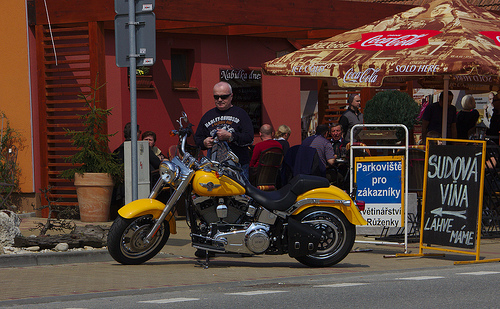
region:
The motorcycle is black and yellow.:
[102, 110, 370, 287]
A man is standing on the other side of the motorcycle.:
[96, 74, 378, 281]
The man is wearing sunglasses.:
[181, 73, 267, 273]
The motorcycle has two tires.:
[105, 102, 370, 278]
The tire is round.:
[281, 196, 357, 271]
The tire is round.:
[91, 197, 176, 272]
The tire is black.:
[104, 191, 183, 286]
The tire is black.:
[261, 181, 366, 281]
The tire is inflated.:
[280, 183, 367, 272]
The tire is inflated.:
[93, 180, 192, 275]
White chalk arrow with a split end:
[426, 203, 470, 222]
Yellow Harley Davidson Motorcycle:
[98, 110, 374, 272]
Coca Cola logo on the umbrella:
[340, 64, 382, 86]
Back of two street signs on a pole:
[109, 1, 160, 236]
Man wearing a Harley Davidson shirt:
[185, 75, 254, 246]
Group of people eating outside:
[104, 63, 499, 248]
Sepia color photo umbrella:
[259, 0, 499, 103]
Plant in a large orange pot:
[50, 76, 136, 230]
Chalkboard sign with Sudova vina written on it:
[407, 129, 490, 273]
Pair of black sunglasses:
[207, 90, 233, 102]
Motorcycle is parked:
[95, 110, 366, 267]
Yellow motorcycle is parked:
[105, 106, 360, 264]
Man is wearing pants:
[200, 152, 257, 190]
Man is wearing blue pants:
[194, 147, 257, 244]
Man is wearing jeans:
[198, 147, 251, 247]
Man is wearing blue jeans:
[200, 152, 254, 247]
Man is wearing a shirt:
[193, 104, 257, 153]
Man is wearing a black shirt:
[185, 105, 261, 167]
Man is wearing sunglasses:
[210, 91, 236, 102]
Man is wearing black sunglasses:
[212, 87, 235, 100]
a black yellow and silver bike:
[102, 123, 365, 278]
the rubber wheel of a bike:
[107, 208, 167, 258]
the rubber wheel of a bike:
[283, 203, 356, 265]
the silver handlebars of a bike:
[176, 124, 225, 172]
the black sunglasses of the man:
[212, 92, 232, 102]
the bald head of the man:
[213, 79, 231, 112]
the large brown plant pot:
[73, 170, 113, 218]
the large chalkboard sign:
[422, 139, 481, 254]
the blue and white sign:
[356, 158, 403, 233]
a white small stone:
[48, 240, 70, 250]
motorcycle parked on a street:
[96, 105, 376, 275]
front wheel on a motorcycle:
[100, 194, 177, 268]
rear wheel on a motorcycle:
[279, 182, 362, 271]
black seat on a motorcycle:
[239, 177, 299, 212]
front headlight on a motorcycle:
[156, 157, 181, 186]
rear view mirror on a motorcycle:
[216, 147, 244, 169]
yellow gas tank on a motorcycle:
[190, 163, 248, 201]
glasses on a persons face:
[210, 90, 234, 101]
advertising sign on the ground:
[411, 130, 498, 270]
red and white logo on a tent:
[343, 25, 446, 55]